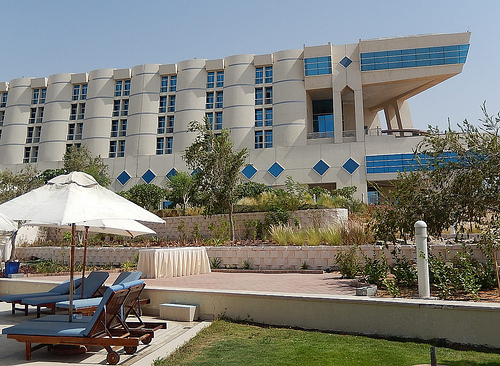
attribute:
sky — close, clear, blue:
[1, 2, 499, 132]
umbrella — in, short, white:
[4, 169, 163, 244]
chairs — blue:
[6, 258, 152, 359]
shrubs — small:
[329, 245, 484, 299]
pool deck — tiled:
[2, 290, 218, 363]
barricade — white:
[411, 217, 451, 295]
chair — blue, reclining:
[3, 274, 85, 313]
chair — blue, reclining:
[17, 269, 109, 313]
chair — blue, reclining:
[55, 268, 143, 313]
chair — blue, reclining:
[33, 278, 168, 332]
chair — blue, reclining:
[3, 284, 143, 364]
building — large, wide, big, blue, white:
[5, 30, 484, 218]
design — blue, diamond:
[312, 158, 331, 176]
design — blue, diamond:
[341, 157, 361, 175]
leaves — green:
[189, 111, 266, 214]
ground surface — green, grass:
[151, 317, 484, 357]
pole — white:
[412, 216, 438, 298]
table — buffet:
[134, 242, 213, 280]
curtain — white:
[134, 244, 213, 279]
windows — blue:
[251, 59, 278, 157]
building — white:
[10, 27, 484, 240]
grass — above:
[262, 219, 309, 240]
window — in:
[251, 83, 276, 107]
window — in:
[251, 55, 276, 93]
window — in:
[249, 123, 276, 157]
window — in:
[247, 61, 276, 87]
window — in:
[151, 81, 185, 117]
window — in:
[249, 105, 277, 127]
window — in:
[253, 122, 280, 150]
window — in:
[253, 101, 279, 128]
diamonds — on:
[237, 159, 289, 189]